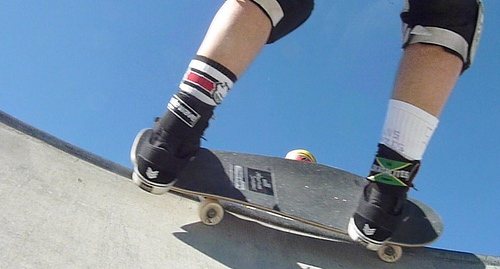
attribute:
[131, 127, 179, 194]
sole — white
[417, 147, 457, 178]
ground — grey, cement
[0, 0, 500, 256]
wall — blue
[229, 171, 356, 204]
skateboard — black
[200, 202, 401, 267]
wheels — white, round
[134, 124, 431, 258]
shoes — black, white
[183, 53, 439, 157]
socks — white, black, red, striped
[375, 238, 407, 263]
wheel — white, round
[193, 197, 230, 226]
wheel — white, round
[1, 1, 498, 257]
sky — blue, clear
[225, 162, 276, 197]
sticker — square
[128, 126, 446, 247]
skateboard — black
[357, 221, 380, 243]
logo — white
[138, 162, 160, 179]
logo — white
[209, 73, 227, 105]
logo — white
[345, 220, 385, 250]
heel — white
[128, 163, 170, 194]
heel — white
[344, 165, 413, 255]
shoe — black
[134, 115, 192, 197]
shoe — black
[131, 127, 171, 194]
sole — white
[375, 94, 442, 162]
white sock — black, red, striped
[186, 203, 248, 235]
wheel — white, round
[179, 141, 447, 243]
skateboard — black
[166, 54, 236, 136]
sock — tall, black, red, white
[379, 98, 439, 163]
sock — white, red, tall, black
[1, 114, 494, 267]
ramp — concrete